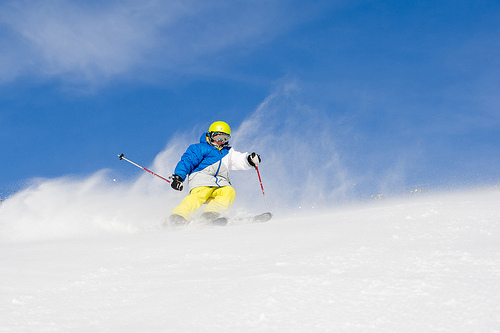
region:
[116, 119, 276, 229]
person snow skiing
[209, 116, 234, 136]
yellow helmet on skier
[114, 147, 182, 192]
ski pole being held by skier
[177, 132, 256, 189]
blue and white jacket worn by skier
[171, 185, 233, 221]
yellow snowpants worn by skier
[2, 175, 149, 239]
snow being kicked up by skis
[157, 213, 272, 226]
snow skis worn by skier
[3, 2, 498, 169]
blue sky with few light clouds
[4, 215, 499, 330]
snow on which skier is snow skiing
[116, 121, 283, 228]
snow skier on snowy slope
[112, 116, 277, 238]
a skier doing stunts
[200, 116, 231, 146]
the bright yellow helmet of a skier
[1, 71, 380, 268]
a big spray of snow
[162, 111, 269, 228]
a skier wearing a blue and white coat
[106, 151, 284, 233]
two red and white ski poles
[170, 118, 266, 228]
a skier wearing bright yellow pants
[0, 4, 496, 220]
an intensely blue sky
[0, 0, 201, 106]
one lone wispy cloud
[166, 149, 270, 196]
warm black skiing gloves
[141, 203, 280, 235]
sturdy skis in the snow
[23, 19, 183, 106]
Blue sky with cirrus clouds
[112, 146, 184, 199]
Ski pole in skier hand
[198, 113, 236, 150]
Yellow florescent skier helmet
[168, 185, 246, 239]
Yellow florescent skier pants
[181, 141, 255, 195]
Blue and white skier jacket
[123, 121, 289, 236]
Skier skiing across a hill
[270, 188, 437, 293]
A snowy hill in winter time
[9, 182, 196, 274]
Snow being kicked up by skier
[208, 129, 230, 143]
Skier cold air goggles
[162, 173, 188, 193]
Skier cold weather sport glove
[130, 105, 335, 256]
a skier skiing down a slope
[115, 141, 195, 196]
a skier's red and white pole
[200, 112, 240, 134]
a yellow ski helmet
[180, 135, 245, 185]
a skier's blue and white coat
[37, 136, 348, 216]
snow kicked up in the air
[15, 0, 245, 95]
a cloud in the sky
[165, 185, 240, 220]
the skier's yellow snow pants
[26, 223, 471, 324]
a snowy slope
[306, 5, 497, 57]
the blue sky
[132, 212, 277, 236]
the person's skis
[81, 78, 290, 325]
Skier on the slopes.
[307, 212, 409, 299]
Snow on the ground.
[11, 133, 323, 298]
Snow blowing in the wind.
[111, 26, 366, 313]
Clear sunny day on the slopes.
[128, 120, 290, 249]
Yellow ski pants.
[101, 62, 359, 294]
Skier with yellow helmet.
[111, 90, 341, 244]
Skier with two ski poles.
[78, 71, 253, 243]
Skier coming down the slope.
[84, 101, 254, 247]
Skier on fresh powder.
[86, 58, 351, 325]
Skier in a white and blue jacket.